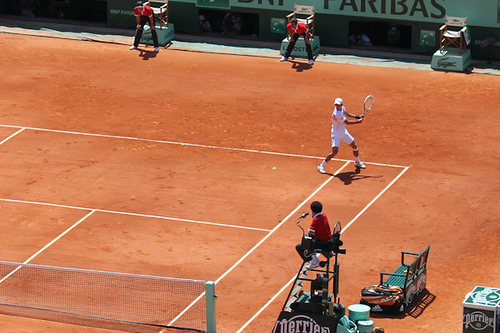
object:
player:
[316, 97, 366, 179]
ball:
[272, 166, 277, 171]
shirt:
[309, 212, 332, 240]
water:
[403, 269, 414, 274]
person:
[130, 2, 159, 54]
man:
[279, 18, 315, 66]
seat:
[438, 17, 472, 55]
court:
[3, 34, 500, 329]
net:
[0, 255, 216, 332]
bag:
[358, 284, 405, 313]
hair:
[310, 200, 323, 213]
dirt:
[3, 35, 500, 332]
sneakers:
[318, 165, 327, 173]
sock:
[319, 159, 328, 167]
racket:
[361, 95, 375, 120]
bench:
[377, 244, 434, 307]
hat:
[334, 98, 343, 105]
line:
[22, 123, 315, 172]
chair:
[283, 221, 344, 326]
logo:
[462, 312, 494, 330]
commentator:
[297, 201, 333, 269]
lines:
[2, 199, 268, 234]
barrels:
[345, 302, 377, 332]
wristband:
[355, 119, 360, 125]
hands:
[301, 36, 311, 45]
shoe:
[353, 160, 366, 168]